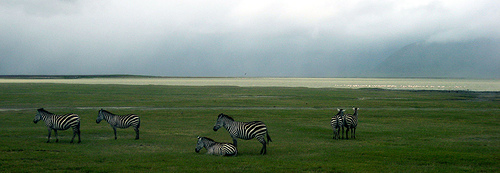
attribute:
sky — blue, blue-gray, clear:
[1, 1, 499, 81]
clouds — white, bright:
[1, 2, 497, 60]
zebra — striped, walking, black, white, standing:
[31, 107, 84, 146]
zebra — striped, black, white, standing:
[94, 106, 142, 143]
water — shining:
[1, 76, 499, 91]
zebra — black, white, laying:
[193, 134, 239, 158]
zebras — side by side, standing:
[326, 105, 360, 142]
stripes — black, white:
[60, 111, 81, 131]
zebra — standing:
[328, 105, 345, 142]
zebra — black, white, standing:
[341, 104, 362, 141]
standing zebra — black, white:
[212, 111, 273, 155]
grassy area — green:
[1, 82, 498, 172]